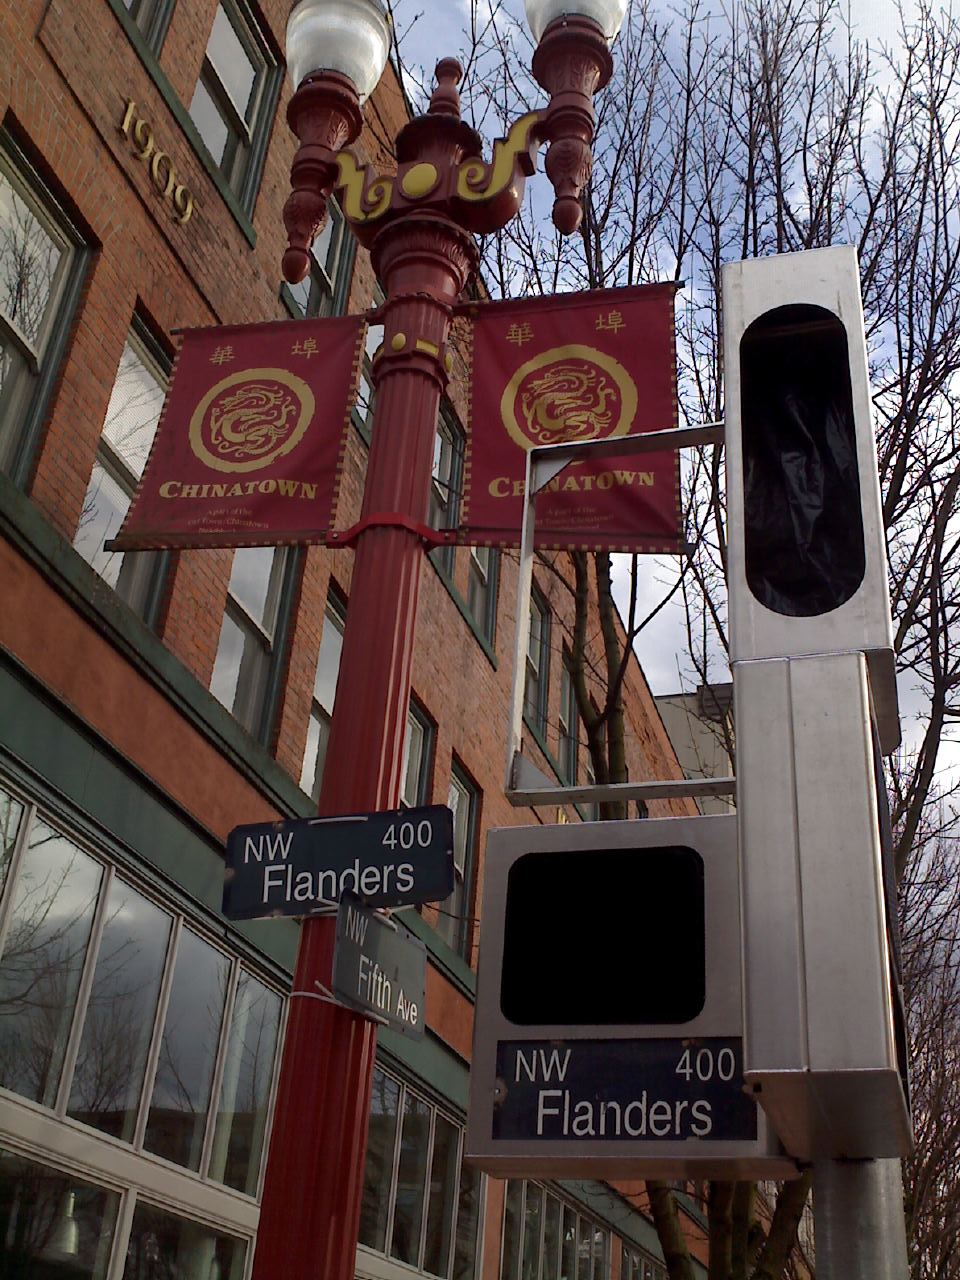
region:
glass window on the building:
[69, 456, 151, 619]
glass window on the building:
[204, 597, 260, 736]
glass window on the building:
[227, 538, 283, 624]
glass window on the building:
[292, 709, 327, 805]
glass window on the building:
[393, 704, 423, 806]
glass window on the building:
[462, 578, 482, 631]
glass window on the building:
[0, 795, 106, 1098]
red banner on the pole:
[465, 288, 688, 528]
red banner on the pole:
[121, 300, 354, 542]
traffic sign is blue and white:
[210, 791, 470, 913]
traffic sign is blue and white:
[498, 1035, 746, 1137]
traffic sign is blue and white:
[318, 889, 446, 1054]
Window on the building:
[14, 811, 114, 1120]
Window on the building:
[113, 291, 154, 587]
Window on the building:
[0, 1148, 130, 1275]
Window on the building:
[373, 1074, 463, 1242]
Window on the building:
[495, 1188, 614, 1278]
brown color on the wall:
[150, 750, 237, 807]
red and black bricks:
[419, 674, 494, 722]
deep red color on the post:
[290, 1041, 353, 1205]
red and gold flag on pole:
[126, 298, 379, 592]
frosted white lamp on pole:
[268, 5, 424, 96]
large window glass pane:
[43, 875, 274, 1178]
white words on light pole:
[502, 1032, 743, 1144]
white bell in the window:
[33, 1172, 115, 1250]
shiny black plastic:
[723, 284, 883, 604]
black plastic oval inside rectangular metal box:
[716, 236, 888, 672]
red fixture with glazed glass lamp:
[272, 1, 395, 283]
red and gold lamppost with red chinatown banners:
[91, 1, 695, 1279]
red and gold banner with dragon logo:
[438, 277, 697, 556]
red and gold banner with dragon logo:
[102, 312, 369, 552]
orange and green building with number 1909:
[0, 1, 817, 1279]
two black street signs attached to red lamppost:
[219, 1, 637, 1276]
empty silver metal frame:
[497, 415, 741, 807]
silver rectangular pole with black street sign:
[459, 244, 917, 1279]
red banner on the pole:
[461, 280, 683, 570]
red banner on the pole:
[102, 300, 361, 592]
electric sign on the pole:
[472, 820, 739, 1029]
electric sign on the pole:
[722, 645, 948, 1159]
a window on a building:
[67, 859, 175, 1160]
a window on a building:
[141, 895, 238, 1178]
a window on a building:
[202, 954, 274, 1204]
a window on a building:
[360, 1050, 402, 1262]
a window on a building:
[390, 1080, 436, 1267]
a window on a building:
[417, 1102, 460, 1274]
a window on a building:
[4, 1143, 127, 1267]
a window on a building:
[120, 1190, 247, 1275]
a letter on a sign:
[535, 1079, 565, 1151]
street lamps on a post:
[267, 6, 618, 1256]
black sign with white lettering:
[223, 816, 458, 913]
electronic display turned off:
[499, 845, 718, 1035]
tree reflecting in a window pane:
[2, 813, 99, 1117]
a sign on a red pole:
[224, 791, 457, 935]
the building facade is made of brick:
[4, 0, 711, 1277]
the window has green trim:
[71, 296, 184, 630]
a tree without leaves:
[405, 6, 954, 715]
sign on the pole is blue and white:
[229, 801, 466, 932]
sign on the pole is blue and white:
[506, 1035, 752, 1140]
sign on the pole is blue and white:
[333, 898, 434, 1036]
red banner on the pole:
[462, 288, 680, 559]